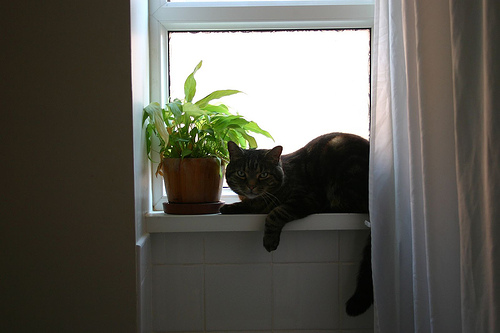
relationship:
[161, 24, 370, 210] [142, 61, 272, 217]
window of houseplant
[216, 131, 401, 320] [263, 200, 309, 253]
cat has leg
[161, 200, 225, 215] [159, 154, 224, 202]
saucer under pot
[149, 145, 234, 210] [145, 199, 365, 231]
pot on sill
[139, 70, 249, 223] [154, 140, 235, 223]
houseplant in a pot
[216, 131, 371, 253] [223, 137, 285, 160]
cat has ears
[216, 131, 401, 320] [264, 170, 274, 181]
cat has an eye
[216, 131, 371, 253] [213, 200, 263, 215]
cat has a leg